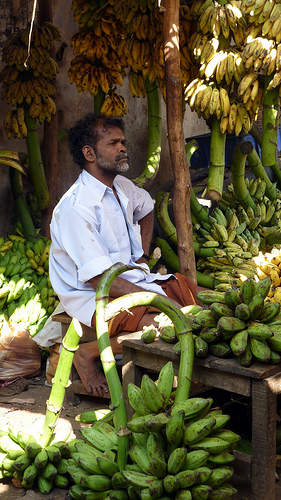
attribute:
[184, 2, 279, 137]
bananas — ripe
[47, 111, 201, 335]
man — selling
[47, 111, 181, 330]
man — pensive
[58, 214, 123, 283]
sleeves — long, rolled up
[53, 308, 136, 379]
stool — holding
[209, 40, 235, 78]
banana — bunch, green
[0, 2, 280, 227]
banana — bunches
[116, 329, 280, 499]
table — rustic, wooden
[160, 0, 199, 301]
pole — middle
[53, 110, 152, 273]
man — seated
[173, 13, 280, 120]
bananas — green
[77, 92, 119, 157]
hair — gray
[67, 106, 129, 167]
hair — curly, black, thinning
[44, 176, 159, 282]
fence — collared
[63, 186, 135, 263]
shirt — white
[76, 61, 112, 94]
bananas — overripe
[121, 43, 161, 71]
bananas — overripe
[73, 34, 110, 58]
bananas — overripe